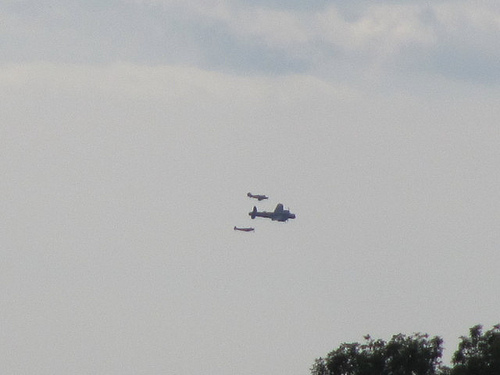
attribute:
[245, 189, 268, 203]
plane — old, higher, small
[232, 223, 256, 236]
plane — old, flat, small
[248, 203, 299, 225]
plane — old, large, big, classic, between`, flanked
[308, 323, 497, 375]
trees — green, dark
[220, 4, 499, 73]
clouds — gray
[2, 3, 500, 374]
sky — gray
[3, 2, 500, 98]
patches — blue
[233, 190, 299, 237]
airplanes — grey, gray, classic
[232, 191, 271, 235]
planes — small